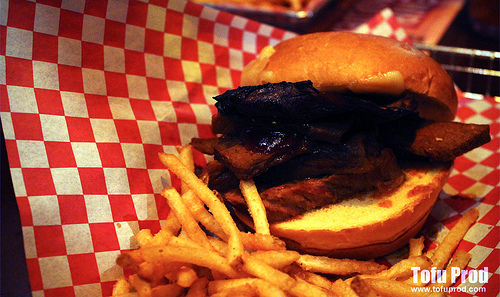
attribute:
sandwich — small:
[144, 7, 423, 258]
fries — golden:
[158, 154, 362, 295]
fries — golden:
[139, 155, 346, 287]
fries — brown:
[109, 140, 484, 295]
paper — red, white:
[63, 85, 144, 157]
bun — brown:
[233, 29, 456, 256]